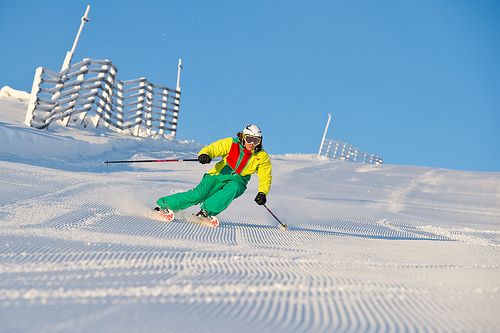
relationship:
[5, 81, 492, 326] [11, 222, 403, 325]
snow has lines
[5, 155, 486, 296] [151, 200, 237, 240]
slope with person sking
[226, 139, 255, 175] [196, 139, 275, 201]
red stripe jacket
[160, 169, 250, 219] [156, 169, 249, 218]
green colored pants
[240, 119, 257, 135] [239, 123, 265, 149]
black on helmet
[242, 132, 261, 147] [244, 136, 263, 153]
goggles on face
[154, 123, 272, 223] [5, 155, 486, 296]
skier on slope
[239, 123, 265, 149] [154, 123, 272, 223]
helmet on skier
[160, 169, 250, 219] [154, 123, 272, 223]
green pants on skier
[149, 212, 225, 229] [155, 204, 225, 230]
white are skis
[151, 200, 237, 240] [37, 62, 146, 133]
sking area gate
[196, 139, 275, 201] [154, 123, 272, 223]
jacket on skier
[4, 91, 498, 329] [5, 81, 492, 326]
mountain has snow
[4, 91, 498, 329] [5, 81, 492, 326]
mountain with snow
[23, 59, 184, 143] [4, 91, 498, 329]
fence on mountain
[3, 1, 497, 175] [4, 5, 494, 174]
cloudless blue sky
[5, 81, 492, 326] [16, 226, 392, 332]
snow shows tracks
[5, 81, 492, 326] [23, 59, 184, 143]
snow with a fence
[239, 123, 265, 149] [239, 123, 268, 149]
helmet on head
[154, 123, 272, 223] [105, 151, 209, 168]
person has a pole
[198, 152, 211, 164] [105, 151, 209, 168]
hand holds a pole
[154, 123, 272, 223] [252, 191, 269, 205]
man has a left hand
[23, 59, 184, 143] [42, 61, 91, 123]
fence caked with snow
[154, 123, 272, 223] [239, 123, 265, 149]
person has a helmet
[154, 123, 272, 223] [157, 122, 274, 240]
skier dressed brightly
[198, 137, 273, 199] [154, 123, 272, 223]
yellow jacket on skier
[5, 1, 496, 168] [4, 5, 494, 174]
blue sky bright